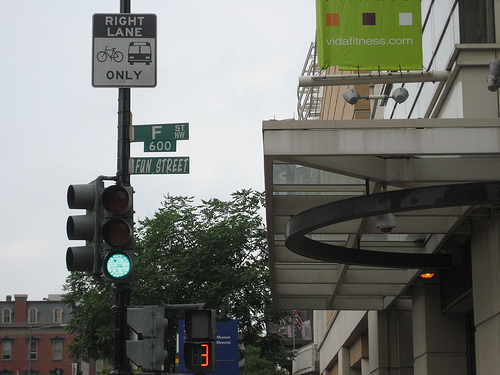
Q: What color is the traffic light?
A: Green.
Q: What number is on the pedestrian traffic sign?
A: Three.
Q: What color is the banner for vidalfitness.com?
A: Green.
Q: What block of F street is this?
A: 600.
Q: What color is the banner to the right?
A: Green.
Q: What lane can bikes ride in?
A: Right lane.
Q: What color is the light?
A: Green.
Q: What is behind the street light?
A: A tree.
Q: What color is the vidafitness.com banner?
A: Green.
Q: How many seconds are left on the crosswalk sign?
A: Three.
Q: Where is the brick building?
A: Bottom, left corner.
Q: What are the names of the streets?
A: F Street and Fun Street.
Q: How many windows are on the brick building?
A: Six.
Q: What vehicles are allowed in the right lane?
A: Bikes and buses.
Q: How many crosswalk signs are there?
A: Two.